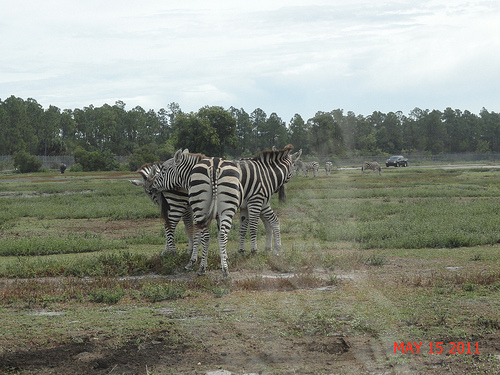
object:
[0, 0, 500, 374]
background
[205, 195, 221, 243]
hair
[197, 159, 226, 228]
tail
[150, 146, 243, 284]
zebra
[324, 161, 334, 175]
animal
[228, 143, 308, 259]
zebra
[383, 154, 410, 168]
car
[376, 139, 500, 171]
parking lot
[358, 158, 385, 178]
zebra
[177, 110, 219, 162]
tree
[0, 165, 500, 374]
field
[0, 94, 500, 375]
outdoors